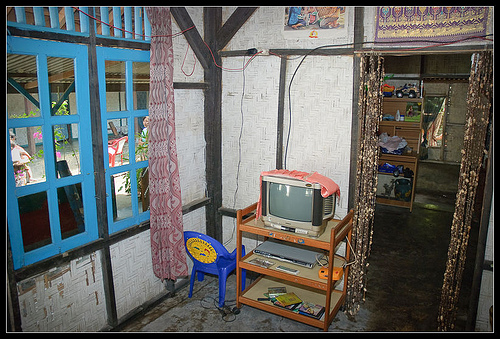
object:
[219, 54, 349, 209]
wall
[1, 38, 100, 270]
window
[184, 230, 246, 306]
chair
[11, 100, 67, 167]
plant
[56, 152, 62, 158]
flowers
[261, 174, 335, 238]
television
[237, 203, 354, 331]
stand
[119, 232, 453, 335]
floor